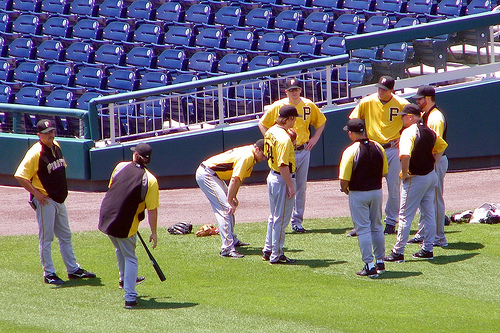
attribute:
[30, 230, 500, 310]
grass — green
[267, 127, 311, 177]
jersey — yellow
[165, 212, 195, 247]
mitt — black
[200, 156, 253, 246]
pants — baseball, white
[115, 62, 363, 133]
railings — metal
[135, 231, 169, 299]
bat — black, baseball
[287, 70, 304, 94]
cap — black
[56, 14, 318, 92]
seating — blue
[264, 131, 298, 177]
shirt — yellow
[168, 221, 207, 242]
glove — black, brown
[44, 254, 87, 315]
shoe — black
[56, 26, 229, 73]
seats — blue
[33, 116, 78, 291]
man — standing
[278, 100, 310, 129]
hat — black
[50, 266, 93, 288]
shoes — black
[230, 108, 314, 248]
player — cricket, baseball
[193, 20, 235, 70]
chair — unoccupied